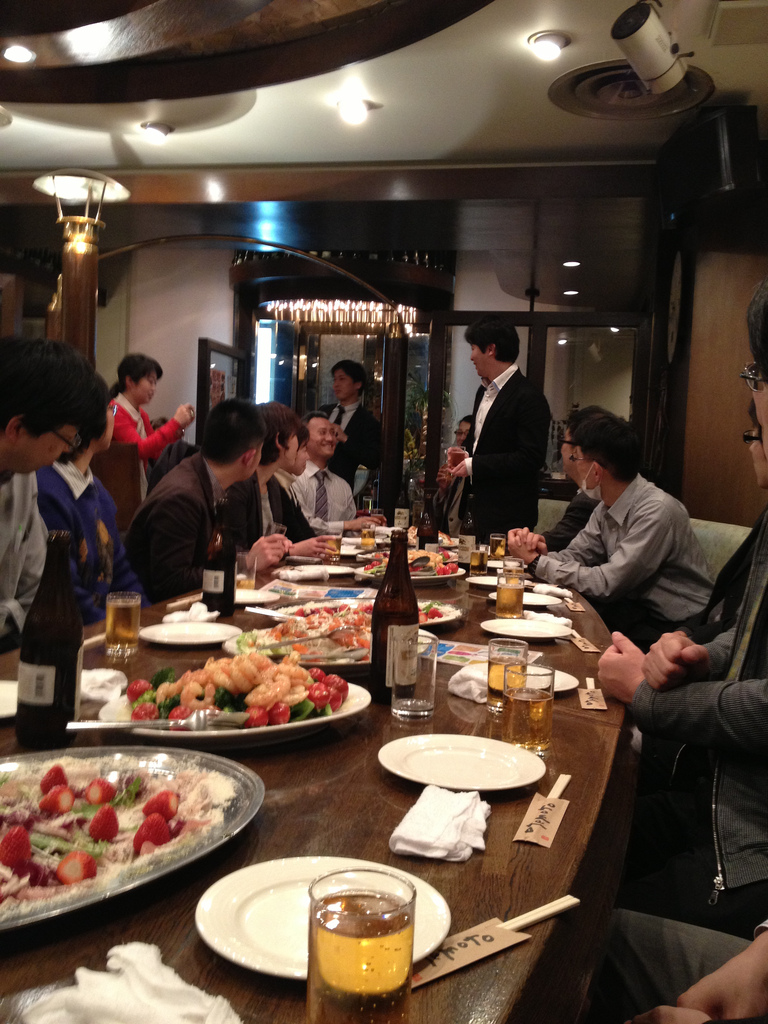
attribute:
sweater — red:
[74, 393, 196, 473]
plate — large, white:
[376, 727, 560, 801]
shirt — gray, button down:
[535, 484, 715, 626]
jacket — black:
[465, 374, 544, 535]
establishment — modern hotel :
[32, 203, 744, 997]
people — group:
[10, 307, 744, 1021]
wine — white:
[373, 530, 423, 708]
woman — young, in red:
[118, 350, 158, 467]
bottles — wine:
[356, 505, 477, 734]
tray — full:
[9, 735, 265, 950]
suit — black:
[461, 382, 567, 543]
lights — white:
[335, 92, 388, 156]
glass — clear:
[292, 853, 466, 1019]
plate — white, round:
[229, 829, 520, 1003]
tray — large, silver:
[18, 723, 337, 984]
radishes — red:
[130, 786, 192, 840]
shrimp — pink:
[151, 650, 361, 736]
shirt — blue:
[30, 463, 204, 571]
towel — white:
[365, 786, 543, 865]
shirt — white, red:
[94, 382, 179, 482]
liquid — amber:
[305, 909, 444, 1016]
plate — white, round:
[164, 837, 471, 1011]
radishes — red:
[42, 800, 136, 900]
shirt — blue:
[27, 459, 183, 620]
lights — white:
[312, 60, 395, 142]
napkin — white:
[361, 768, 488, 897]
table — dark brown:
[10, 509, 652, 1020]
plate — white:
[389, 685, 620, 860]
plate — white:
[375, 731, 546, 791]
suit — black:
[464, 368, 549, 527]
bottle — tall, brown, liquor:
[367, 525, 420, 712]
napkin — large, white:
[384, 779, 490, 864]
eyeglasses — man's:
[51, 427, 84, 452]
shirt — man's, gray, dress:
[536, 469, 718, 626]